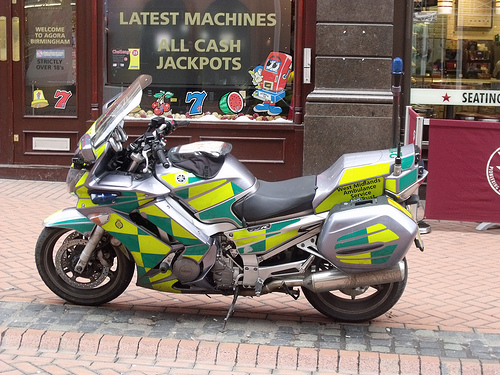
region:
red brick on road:
[1, 320, 26, 352]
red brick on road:
[18, 323, 41, 348]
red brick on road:
[38, 327, 65, 357]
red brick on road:
[58, 326, 80, 356]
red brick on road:
[79, 329, 101, 359]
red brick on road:
[93, 330, 121, 356]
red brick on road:
[121, 335, 138, 366]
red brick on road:
[136, 332, 163, 362]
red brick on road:
[158, 329, 183, 372]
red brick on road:
[173, 332, 198, 369]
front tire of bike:
[33, 206, 135, 301]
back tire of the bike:
[278, 220, 425, 340]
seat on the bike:
[210, 137, 367, 230]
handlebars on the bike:
[120, 97, 192, 177]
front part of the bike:
[31, 68, 158, 222]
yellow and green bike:
[128, 190, 224, 272]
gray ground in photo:
[117, 305, 196, 346]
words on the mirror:
[91, 2, 286, 79]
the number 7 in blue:
[175, 84, 210, 128]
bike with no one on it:
[26, 43, 459, 335]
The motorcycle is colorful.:
[32, 47, 432, 346]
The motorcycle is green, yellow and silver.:
[21, 68, 446, 350]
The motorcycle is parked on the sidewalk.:
[14, 62, 471, 372]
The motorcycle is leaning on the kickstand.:
[20, 65, 440, 349]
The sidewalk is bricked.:
[2, 151, 499, 371]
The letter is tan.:
[151, 53, 166, 70]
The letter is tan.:
[161, 54, 176, 71]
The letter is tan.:
[186, 53, 201, 72]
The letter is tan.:
[198, 54, 210, 71]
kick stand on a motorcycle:
[221, 278, 241, 324]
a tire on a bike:
[32, 222, 108, 317]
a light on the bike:
[389, 54, 406, 119]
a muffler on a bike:
[278, 261, 385, 292]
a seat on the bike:
[246, 161, 319, 217]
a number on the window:
[49, 84, 74, 117]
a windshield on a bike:
[82, 90, 150, 152]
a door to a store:
[9, 9, 82, 147]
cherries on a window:
[152, 79, 175, 121]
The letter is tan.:
[116, 9, 130, 29]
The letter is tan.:
[168, 35, 180, 56]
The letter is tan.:
[178, 34, 192, 56]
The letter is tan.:
[194, 31, 206, 53]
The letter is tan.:
[203, 35, 218, 52]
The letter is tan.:
[217, 37, 230, 55]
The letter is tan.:
[226, 37, 247, 54]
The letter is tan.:
[198, 55, 210, 75]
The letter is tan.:
[220, 54, 233, 71]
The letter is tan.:
[229, 55, 244, 72]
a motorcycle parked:
[28, 68, 440, 338]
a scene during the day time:
[0, 1, 497, 370]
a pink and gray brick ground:
[7, 170, 499, 373]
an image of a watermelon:
[213, 85, 250, 125]